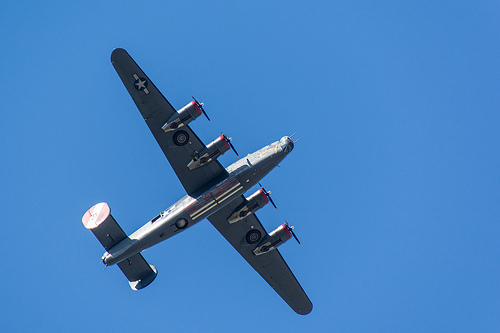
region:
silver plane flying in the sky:
[78, 45, 315, 319]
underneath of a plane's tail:
[78, 198, 162, 293]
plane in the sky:
[78, 43, 319, 318]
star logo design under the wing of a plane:
[122, 68, 152, 98]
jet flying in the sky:
[80, 46, 321, 320]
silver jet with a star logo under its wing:
[80, 43, 315, 320]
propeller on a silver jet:
[155, 90, 213, 135]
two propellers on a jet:
[157, 88, 249, 170]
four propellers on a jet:
[158, 95, 305, 260]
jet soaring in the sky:
[78, 43, 320, 318]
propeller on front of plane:
[186, 94, 212, 114]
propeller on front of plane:
[209, 129, 243, 157]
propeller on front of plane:
[257, 182, 278, 209]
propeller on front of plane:
[277, 217, 306, 244]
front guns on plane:
[277, 132, 302, 150]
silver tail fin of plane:
[85, 208, 153, 284]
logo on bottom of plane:
[171, 132, 189, 149]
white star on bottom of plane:
[130, 73, 150, 91]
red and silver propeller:
[157, 100, 205, 134]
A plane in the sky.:
[83, 45, 313, 303]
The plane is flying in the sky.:
[52, 44, 337, 301]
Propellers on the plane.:
[175, 89, 265, 151]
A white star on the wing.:
[128, 70, 165, 93]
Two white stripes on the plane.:
[178, 186, 247, 224]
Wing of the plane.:
[106, 42, 213, 172]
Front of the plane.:
[278, 138, 310, 170]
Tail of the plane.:
[86, 201, 167, 278]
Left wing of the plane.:
[213, 202, 353, 311]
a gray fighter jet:
[59, 35, 359, 327]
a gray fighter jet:
[54, 35, 338, 325]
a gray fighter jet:
[21, 39, 356, 329]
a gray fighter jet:
[50, 48, 332, 329]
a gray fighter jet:
[51, 23, 341, 331]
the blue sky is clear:
[306, 97, 426, 267]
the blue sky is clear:
[193, 15, 347, 152]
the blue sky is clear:
[33, 85, 168, 252]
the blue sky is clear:
[351, 93, 491, 273]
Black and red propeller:
[185, 86, 222, 128]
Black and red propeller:
[212, 120, 242, 163]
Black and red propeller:
[257, 176, 290, 207]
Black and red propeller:
[274, 201, 311, 247]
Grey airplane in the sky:
[53, 24, 351, 331]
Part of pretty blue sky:
[384, 279, 419, 319]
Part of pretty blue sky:
[428, 256, 478, 326]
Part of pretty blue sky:
[345, 164, 392, 227]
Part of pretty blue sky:
[413, 147, 470, 233]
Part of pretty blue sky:
[309, 32, 376, 102]